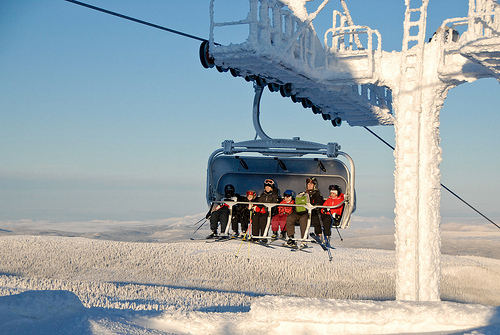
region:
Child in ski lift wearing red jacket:
[311, 181, 346, 257]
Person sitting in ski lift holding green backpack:
[285, 175, 321, 248]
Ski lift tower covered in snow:
[205, 0, 495, 295]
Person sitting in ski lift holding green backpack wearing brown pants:
[280, 170, 320, 250]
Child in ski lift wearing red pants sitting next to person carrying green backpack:
[263, 187, 296, 243]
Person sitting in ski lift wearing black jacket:
[250, 175, 275, 250]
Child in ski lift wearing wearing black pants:
[228, 188, 257, 244]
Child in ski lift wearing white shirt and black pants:
[198, 183, 236, 241]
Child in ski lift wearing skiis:
[310, 180, 346, 254]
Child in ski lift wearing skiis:
[230, 183, 256, 243]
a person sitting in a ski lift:
[201, 183, 239, 240]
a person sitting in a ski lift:
[230, 186, 255, 236]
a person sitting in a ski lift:
[252, 173, 277, 238]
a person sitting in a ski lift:
[272, 186, 297, 242]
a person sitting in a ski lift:
[287, 178, 322, 246]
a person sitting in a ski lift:
[317, 183, 344, 247]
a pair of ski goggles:
[262, 176, 274, 186]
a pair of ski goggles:
[305, 174, 320, 184]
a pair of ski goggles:
[327, 185, 339, 193]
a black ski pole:
[330, 213, 347, 240]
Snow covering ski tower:
[204, 0, 499, 310]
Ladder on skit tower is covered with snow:
[397, 0, 424, 302]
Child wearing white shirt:
[204, 179, 238, 242]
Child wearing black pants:
[232, 187, 256, 235]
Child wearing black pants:
[312, 181, 344, 246]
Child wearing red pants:
[267, 183, 300, 246]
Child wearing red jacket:
[267, 186, 296, 241]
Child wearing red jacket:
[310, 181, 350, 246]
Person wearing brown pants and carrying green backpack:
[286, 178, 323, 253]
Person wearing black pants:
[248, 178, 281, 243]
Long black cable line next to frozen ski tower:
[67, 0, 497, 230]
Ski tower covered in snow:
[207, 0, 498, 303]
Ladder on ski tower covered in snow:
[400, 0, 426, 297]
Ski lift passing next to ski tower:
[202, 82, 361, 249]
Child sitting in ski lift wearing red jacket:
[310, 183, 347, 239]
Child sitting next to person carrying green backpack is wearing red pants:
[270, 189, 297, 241]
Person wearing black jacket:
[245, 173, 280, 246]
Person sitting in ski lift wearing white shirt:
[205, 184, 240, 241]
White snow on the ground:
[126, 264, 239, 304]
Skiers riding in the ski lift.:
[196, 175, 349, 244]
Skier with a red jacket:
[312, 185, 344, 249]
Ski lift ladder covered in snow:
[390, 5, 422, 297]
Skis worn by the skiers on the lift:
[193, 230, 330, 252]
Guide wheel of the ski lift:
[193, 37, 222, 68]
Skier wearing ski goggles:
[261, 178, 278, 188]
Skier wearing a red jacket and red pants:
[272, 190, 297, 237]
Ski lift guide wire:
[85, 5, 205, 41]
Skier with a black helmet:
[222, 183, 237, 197]